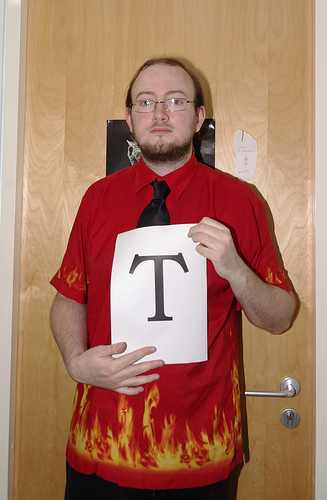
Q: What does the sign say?
A: T.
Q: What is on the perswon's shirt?
A: Flames.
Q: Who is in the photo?
A: A man.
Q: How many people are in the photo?
A: One.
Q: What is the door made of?
A: Wood.